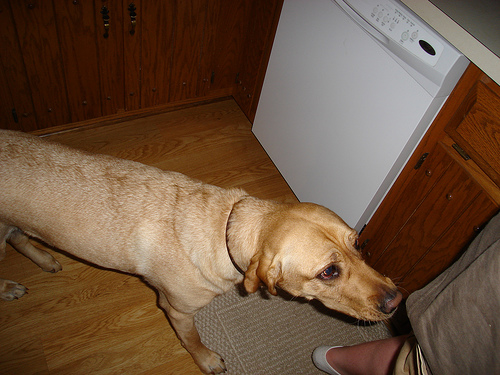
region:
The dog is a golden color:
[6, 120, 416, 370]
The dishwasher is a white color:
[269, 0, 466, 275]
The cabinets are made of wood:
[7, 4, 242, 124]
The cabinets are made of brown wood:
[1, 35, 243, 135]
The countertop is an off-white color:
[403, 3, 498, 93]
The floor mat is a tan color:
[181, 278, 417, 371]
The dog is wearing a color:
[214, 175, 264, 295]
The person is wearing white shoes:
[302, 333, 355, 370]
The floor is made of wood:
[14, 295, 166, 360]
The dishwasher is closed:
[242, 3, 464, 234]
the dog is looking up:
[140, 165, 417, 371]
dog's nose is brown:
[375, 266, 411, 328]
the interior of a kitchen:
[0, 0, 499, 374]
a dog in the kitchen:
[0, 128, 402, 373]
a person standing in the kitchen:
[311, 211, 498, 373]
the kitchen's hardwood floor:
[0, 98, 395, 374]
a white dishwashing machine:
[250, 0, 470, 236]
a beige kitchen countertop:
[400, 0, 498, 85]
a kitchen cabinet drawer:
[442, 79, 499, 187]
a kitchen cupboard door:
[361, 141, 498, 299]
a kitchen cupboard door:
[120, 0, 221, 112]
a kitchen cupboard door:
[0, 0, 119, 132]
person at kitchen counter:
[311, 210, 499, 373]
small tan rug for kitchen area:
[186, 256, 406, 373]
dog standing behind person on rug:
[2, 126, 407, 373]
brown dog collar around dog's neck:
[222, 193, 249, 278]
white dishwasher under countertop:
[248, 0, 473, 242]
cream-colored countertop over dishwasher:
[405, 0, 499, 87]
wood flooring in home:
[2, 88, 300, 373]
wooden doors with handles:
[0, 0, 286, 135]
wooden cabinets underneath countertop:
[350, 57, 497, 302]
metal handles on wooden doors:
[98, 3, 141, 41]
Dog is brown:
[4, 122, 421, 373]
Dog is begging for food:
[3, 112, 433, 373]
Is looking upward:
[308, 220, 367, 289]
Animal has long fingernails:
[18, 248, 72, 313]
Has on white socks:
[299, 325, 366, 372]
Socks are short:
[303, 336, 353, 373]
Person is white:
[335, 324, 435, 374]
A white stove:
[241, 3, 462, 313]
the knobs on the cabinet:
[60, 3, 197, 64]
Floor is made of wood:
[50, 299, 151, 361]